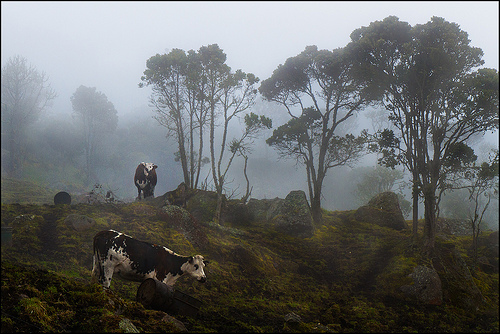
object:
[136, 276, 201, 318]
barrel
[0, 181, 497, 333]
hillside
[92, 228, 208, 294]
cow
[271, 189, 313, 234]
rock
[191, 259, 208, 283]
face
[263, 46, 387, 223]
tree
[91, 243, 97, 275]
tail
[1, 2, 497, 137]
sky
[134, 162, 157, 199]
cow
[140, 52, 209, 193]
tree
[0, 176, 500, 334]
grass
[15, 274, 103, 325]
moss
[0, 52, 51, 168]
trees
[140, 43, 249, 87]
tops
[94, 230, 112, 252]
bottom